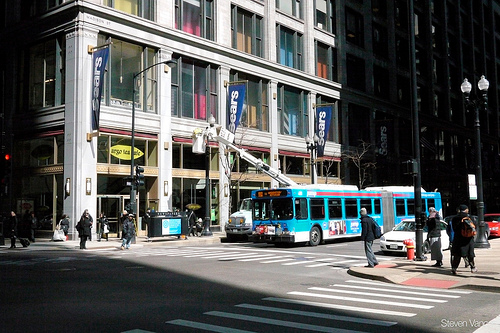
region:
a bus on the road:
[194, 111, 401, 318]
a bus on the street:
[200, 168, 392, 287]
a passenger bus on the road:
[254, 168, 451, 311]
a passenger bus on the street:
[273, 146, 482, 316]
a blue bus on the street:
[232, 166, 494, 289]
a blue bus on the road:
[242, 161, 489, 263]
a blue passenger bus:
[258, 166, 460, 278]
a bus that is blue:
[287, 138, 486, 279]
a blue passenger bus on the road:
[248, 161, 499, 276]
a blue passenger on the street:
[254, 114, 477, 271]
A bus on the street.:
[248, 182, 457, 235]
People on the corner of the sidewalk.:
[388, 198, 495, 270]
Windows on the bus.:
[308, 198, 363, 219]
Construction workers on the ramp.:
[185, 114, 291, 176]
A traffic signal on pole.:
[124, 152, 146, 187]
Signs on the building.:
[302, 90, 334, 163]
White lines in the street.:
[189, 242, 329, 287]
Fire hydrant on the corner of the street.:
[396, 232, 423, 261]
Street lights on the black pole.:
[456, 76, 493, 208]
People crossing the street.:
[68, 196, 145, 249]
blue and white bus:
[252, 183, 441, 243]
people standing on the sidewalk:
[355, 201, 480, 265]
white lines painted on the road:
[124, 233, 482, 325]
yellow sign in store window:
[107, 142, 142, 162]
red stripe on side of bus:
[316, 186, 407, 198]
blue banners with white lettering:
[228, 84, 335, 148]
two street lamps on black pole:
[449, 74, 491, 246]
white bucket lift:
[188, 122, 295, 186]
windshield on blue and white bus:
[251, 198, 288, 218]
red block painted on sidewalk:
[407, 271, 452, 288]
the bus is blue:
[244, 190, 444, 242]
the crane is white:
[193, 121, 297, 190]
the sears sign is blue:
[88, 47, 107, 132]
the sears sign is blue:
[223, 78, 247, 138]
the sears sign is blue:
[311, 103, 329, 149]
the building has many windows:
[30, 16, 335, 236]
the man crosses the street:
[358, 205, 380, 268]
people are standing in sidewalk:
[423, 208, 473, 274]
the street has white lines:
[0, 238, 498, 330]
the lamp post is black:
[127, 60, 176, 215]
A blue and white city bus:
[247, 185, 444, 247]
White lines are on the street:
[116, 244, 474, 331]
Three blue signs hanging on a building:
[86, 40, 334, 160]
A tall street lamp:
[457, 71, 490, 251]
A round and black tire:
[306, 223, 323, 250]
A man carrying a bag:
[448, 202, 477, 277]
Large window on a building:
[166, 50, 224, 129]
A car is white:
[379, 214, 453, 254]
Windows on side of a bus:
[293, 194, 437, 221]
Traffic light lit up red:
[1, 150, 15, 177]